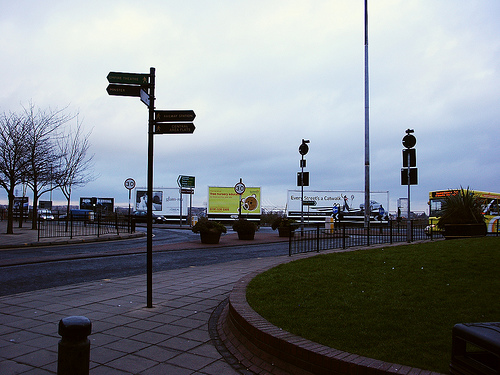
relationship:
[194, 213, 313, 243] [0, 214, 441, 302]
flowers beside road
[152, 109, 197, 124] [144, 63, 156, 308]
sign on pole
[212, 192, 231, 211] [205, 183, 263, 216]
advertisement on sign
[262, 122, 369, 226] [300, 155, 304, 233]
three signs on pole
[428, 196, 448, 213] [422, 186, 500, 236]
front windshield of bus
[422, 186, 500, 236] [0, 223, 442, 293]
bus on road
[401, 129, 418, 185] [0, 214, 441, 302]
signal beside road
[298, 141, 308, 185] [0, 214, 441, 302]
signal beside road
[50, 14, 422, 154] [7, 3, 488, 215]
clouds in sky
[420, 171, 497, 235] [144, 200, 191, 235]
bus on road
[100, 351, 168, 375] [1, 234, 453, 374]
stone on walkway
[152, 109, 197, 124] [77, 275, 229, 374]
sign on walkway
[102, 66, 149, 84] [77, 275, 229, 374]
sign on walkway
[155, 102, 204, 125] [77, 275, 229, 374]
sign on walkway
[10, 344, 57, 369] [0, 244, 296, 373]
stone in walkway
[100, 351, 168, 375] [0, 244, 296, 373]
stone in walkway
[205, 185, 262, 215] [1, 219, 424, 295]
billboard along street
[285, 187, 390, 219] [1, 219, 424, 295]
billboard along street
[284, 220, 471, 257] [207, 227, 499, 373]
metal fence along park square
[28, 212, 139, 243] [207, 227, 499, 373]
metal fence along park square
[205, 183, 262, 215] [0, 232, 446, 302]
billboard across road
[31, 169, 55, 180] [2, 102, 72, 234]
leaves on a tree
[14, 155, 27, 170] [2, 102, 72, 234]
leaves on a tree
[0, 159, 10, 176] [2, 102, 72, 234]
leaves on a tree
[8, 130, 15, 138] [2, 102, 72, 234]
leaves on a tree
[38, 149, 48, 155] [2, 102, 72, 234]
leaves on a tree